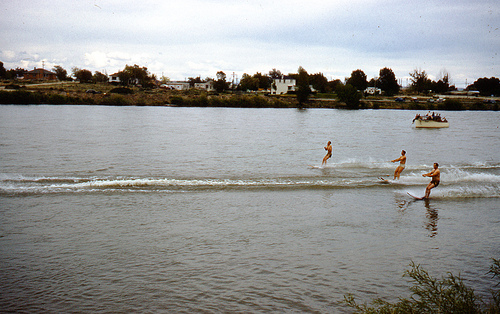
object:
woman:
[319, 137, 332, 168]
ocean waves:
[453, 166, 490, 199]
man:
[321, 139, 333, 169]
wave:
[404, 185, 499, 198]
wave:
[5, 171, 93, 181]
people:
[314, 136, 341, 165]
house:
[269, 76, 309, 93]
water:
[10, 100, 486, 292]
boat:
[406, 109, 448, 129]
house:
[361, 83, 382, 95]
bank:
[355, 98, 393, 102]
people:
[411, 109, 447, 121]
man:
[389, 149, 414, 178]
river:
[4, 107, 496, 311]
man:
[417, 162, 448, 197]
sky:
[82, 0, 479, 109]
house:
[161, 75, 219, 91]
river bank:
[27, 72, 489, 107]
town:
[4, 56, 498, 113]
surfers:
[393, 149, 408, 180]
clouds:
[20, 8, 369, 80]